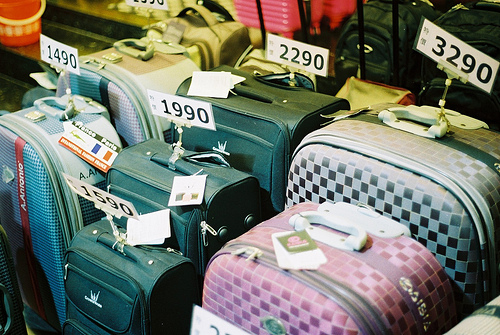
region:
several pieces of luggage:
[2, 18, 492, 333]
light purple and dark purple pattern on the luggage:
[174, 204, 459, 332]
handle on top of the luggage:
[291, 208, 373, 249]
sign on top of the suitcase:
[143, 88, 222, 163]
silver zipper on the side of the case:
[198, 212, 220, 245]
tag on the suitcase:
[59, 116, 128, 174]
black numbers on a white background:
[263, 34, 331, 81]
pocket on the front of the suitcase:
[56, 260, 140, 333]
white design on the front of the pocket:
[77, 282, 117, 312]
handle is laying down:
[113, 33, 152, 63]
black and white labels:
[250, 32, 327, 82]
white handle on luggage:
[295, 205, 363, 264]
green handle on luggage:
[145, 145, 199, 188]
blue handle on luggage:
[25, 91, 84, 131]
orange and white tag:
[44, 111, 116, 178]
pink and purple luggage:
[220, 202, 467, 316]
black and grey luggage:
[285, 102, 499, 245]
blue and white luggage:
[1, 84, 119, 288]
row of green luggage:
[61, 80, 318, 327]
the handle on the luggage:
[377, 104, 448, 136]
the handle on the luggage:
[288, 210, 367, 252]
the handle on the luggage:
[33, 95, 73, 120]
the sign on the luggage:
[416, 18, 498, 93]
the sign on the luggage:
[265, 32, 327, 77]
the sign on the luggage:
[147, 90, 214, 130]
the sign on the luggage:
[39, 33, 79, 75]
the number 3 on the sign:
[432, 36, 447, 56]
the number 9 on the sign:
[171, 100, 183, 117]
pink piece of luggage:
[248, 198, 373, 332]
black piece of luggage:
[80, 223, 162, 313]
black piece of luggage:
[116, 118, 258, 233]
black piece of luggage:
[200, 78, 287, 160]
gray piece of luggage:
[24, 130, 102, 289]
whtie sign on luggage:
[167, 100, 209, 121]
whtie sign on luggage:
[254, 30, 323, 74]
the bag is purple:
[213, 207, 439, 332]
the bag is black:
[71, 227, 183, 334]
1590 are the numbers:
[81, 180, 135, 217]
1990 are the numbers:
[152, 95, 225, 135]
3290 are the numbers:
[425, 35, 496, 94]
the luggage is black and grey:
[296, 129, 486, 230]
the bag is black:
[191, 69, 317, 151]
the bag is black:
[337, 2, 404, 88]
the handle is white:
[293, 204, 386, 248]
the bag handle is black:
[354, 8, 407, 78]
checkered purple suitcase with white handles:
[201, 198, 458, 334]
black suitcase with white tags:
[172, 63, 352, 212]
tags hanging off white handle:
[272, 209, 367, 278]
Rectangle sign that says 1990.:
[146, 90, 217, 130]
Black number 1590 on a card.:
[81, 184, 133, 216]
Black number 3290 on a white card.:
[433, 34, 493, 84]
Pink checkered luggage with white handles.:
[201, 199, 458, 334]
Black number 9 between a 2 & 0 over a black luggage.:
[301, 50, 311, 67]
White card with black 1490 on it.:
[37, 34, 80, 76]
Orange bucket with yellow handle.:
[1, 1, 46, 45]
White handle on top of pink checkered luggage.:
[290, 211, 368, 252]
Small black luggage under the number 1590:
[60, 216, 200, 333]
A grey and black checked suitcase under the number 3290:
[284, 101, 499, 316]